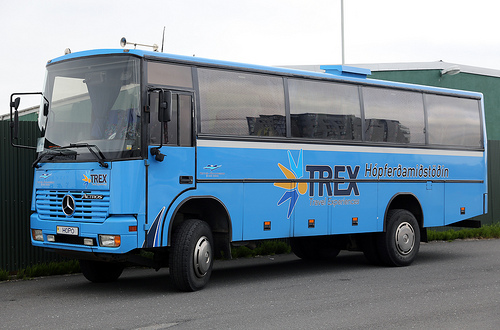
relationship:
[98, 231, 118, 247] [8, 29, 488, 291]
headlight of bus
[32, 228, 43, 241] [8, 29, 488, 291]
headlight of bus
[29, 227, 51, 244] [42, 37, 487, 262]
headlight of bus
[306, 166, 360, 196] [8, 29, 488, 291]
trex written on front of bus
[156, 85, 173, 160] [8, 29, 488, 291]
rearview mirror on bus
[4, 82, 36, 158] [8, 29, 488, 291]
mirror on bus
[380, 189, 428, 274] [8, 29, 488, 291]
tire on bus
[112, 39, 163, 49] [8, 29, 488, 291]
horn on top of bus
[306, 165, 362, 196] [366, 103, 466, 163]
letter on bus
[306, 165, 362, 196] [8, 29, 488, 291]
letter on bus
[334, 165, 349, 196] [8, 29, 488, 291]
letter on bus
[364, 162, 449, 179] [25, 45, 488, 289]
letter on bus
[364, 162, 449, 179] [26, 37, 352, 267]
letter on bus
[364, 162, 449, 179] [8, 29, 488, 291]
letter on bus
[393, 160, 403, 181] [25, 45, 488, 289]
letter on bus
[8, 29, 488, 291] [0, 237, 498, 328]
bus parked in road